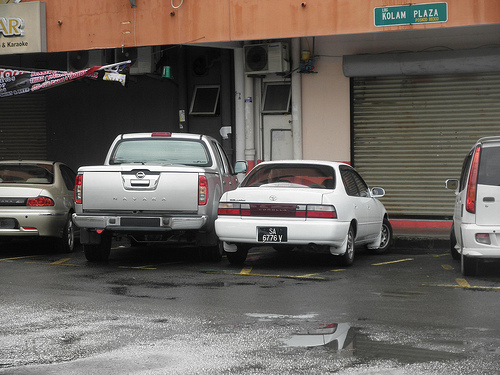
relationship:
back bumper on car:
[213, 215, 339, 247] [215, 159, 393, 266]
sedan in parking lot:
[2, 160, 73, 251] [0, 234, 500, 373]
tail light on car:
[213, 196, 335, 226] [209, 148, 405, 271]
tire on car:
[371, 210, 401, 255] [218, 143, 427, 288]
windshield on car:
[239, 162, 336, 187] [215, 159, 393, 266]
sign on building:
[374, 0, 447, 28] [1, 0, 499, 218]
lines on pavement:
[4, 243, 486, 286] [13, 222, 498, 369]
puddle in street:
[323, 312, 439, 363] [4, 237, 498, 373]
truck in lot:
[70, 119, 243, 281] [0, 238, 498, 373]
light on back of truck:
[198, 175, 209, 207] [68, 132, 237, 268]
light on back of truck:
[74, 173, 83, 202] [68, 132, 237, 268]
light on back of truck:
[198, 175, 208, 207] [71, 130, 246, 264]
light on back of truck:
[73, 171, 84, 203] [71, 130, 246, 264]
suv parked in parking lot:
[446, 133, 498, 280] [3, 25, 497, 373]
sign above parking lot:
[374, 2, 449, 26] [0, 234, 500, 373]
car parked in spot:
[215, 159, 393, 266] [175, 211, 442, 307]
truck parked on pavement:
[73, 132, 247, 262] [13, 222, 498, 369]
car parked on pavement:
[215, 159, 393, 266] [13, 222, 498, 369]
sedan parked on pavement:
[0, 160, 73, 248] [13, 222, 498, 369]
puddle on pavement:
[323, 312, 439, 363] [13, 222, 498, 369]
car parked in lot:
[215, 146, 377, 263] [6, 247, 498, 369]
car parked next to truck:
[215, 159, 393, 266] [71, 130, 246, 264]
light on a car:
[290, 205, 340, 222] [215, 159, 393, 266]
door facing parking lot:
[335, 51, 489, 192] [4, 258, 490, 364]